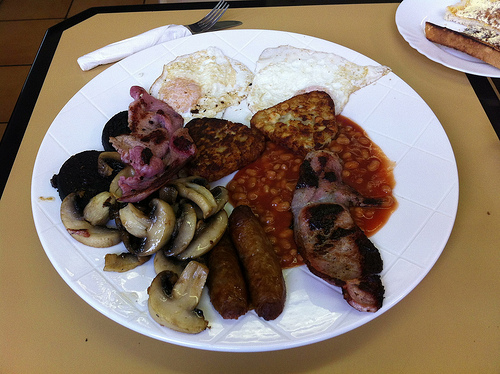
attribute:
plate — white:
[31, 28, 459, 354]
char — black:
[351, 235, 386, 295]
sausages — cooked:
[207, 207, 283, 320]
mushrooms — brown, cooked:
[61, 180, 228, 332]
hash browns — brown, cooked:
[187, 90, 337, 177]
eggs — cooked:
[157, 44, 352, 120]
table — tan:
[0, 1, 499, 372]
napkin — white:
[75, 23, 190, 69]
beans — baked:
[230, 115, 396, 263]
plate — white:
[394, 2, 499, 78]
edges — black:
[0, 15, 68, 155]